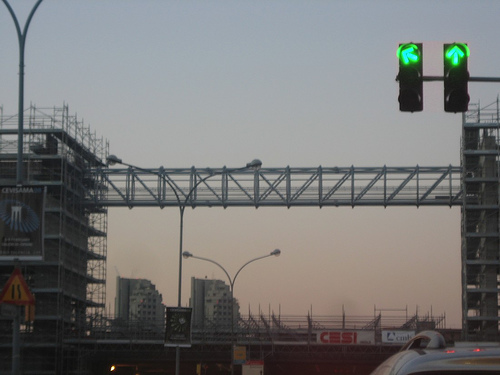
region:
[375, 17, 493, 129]
green arrows on light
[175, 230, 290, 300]
two lights hanging in the air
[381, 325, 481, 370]
top part of vehicle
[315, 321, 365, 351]
red letters on a white background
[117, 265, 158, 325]
building in the background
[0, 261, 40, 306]
yellow sign with red border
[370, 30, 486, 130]
two green lights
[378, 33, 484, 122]
two arrows pointing different ways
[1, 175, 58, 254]
sign on a pole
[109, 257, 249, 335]
two buildings next to each other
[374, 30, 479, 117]
two green stoplights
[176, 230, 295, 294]
two lights facing opposite directions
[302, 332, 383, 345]
a white sign with red lettering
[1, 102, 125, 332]
a tall building under construction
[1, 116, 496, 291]
two buildings under construction with a walkway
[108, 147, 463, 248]
a walkway that passes over a road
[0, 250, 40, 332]
a triangular shaped street sign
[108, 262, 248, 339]
two identical buildings beside each other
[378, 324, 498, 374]
the top of a car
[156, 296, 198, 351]
a black sign with a circular shape on it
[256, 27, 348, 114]
part of the sky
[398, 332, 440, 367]
top of a car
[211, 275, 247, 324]
part of a post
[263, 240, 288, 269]
part of a lamp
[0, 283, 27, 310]
edge of a sign board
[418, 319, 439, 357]
part of a handle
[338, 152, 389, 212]
part of a bridge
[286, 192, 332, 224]
edge of a bridge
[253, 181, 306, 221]
part of a metal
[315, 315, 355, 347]
part of a banner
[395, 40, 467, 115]
Two traffic lights are green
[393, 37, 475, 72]
Green lights are arrows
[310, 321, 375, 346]
White sign with red lettering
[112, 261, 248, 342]
Two tall similar buildings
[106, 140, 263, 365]
Street light with sign on bottom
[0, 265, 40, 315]
Cation road sign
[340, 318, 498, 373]
Top of vehicle in lower right corner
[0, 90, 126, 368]
Scaffold around building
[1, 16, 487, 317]
Dim sky is clear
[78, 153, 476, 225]
Structure between two buildings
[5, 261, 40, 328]
a traffic sign with black lines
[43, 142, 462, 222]
a walkway connecting two buildings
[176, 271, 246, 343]
a tall building with several windows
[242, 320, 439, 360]
two signs with letters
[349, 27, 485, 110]
two traffic lights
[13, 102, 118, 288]
a building under construction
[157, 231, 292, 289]
a tall pole with two street lights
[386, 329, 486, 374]
the top of a vehicle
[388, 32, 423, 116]
a traffic light showing a green arrow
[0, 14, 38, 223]
a tall metal pole